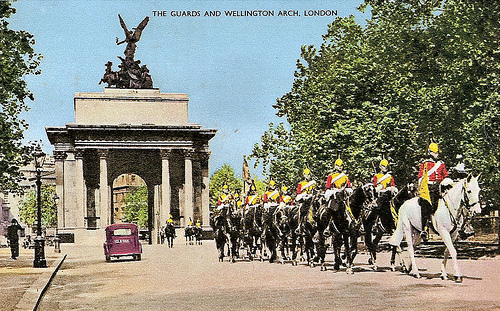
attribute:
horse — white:
[392, 172, 482, 282]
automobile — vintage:
[90, 219, 148, 260]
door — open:
[112, 164, 151, 227]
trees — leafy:
[237, 0, 499, 202]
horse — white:
[390, 167, 486, 289]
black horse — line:
[311, 172, 393, 272]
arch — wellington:
[78, 152, 230, 271]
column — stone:
[75, 144, 107, 231]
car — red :
[103, 223, 143, 265]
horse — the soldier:
[389, 176, 489, 286]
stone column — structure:
[156, 149, 174, 236]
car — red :
[102, 219, 144, 263]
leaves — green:
[300, 7, 499, 167]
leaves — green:
[0, 2, 37, 233]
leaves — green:
[28, 174, 158, 231]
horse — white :
[386, 167, 482, 283]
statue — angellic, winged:
[98, 15, 159, 90]